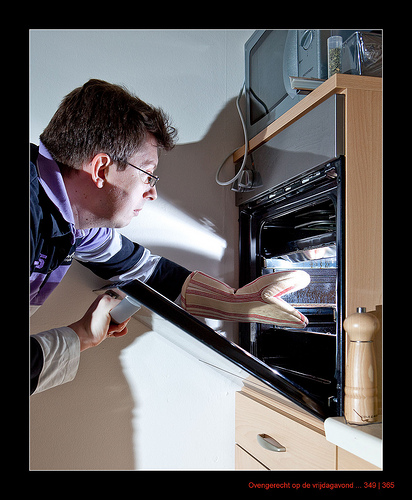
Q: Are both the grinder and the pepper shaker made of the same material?
A: Yes, both the grinder and the pepper shaker are made of wood.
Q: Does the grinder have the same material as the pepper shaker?
A: Yes, both the grinder and the pepper shaker are made of wood.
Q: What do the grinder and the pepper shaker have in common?
A: The material, both the grinder and the pepper shaker are wooden.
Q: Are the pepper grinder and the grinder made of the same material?
A: Yes, both the pepper grinder and the grinder are made of wood.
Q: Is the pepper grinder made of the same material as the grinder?
A: Yes, both the pepper grinder and the grinder are made of wood.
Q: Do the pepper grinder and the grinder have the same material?
A: Yes, both the pepper grinder and the grinder are made of wood.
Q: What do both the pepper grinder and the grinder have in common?
A: The material, both the pepper grinder and the grinder are wooden.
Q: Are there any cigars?
A: No, there are no cigars.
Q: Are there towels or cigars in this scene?
A: No, there are no cigars or towels.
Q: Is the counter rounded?
A: Yes, the counter is rounded.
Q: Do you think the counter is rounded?
A: Yes, the counter is rounded.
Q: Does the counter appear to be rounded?
A: Yes, the counter is rounded.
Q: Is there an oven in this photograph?
A: Yes, there is an oven.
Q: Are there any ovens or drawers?
A: Yes, there is an oven.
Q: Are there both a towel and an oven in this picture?
A: No, there is an oven but no towels.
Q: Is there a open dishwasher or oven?
A: Yes, there is an open oven.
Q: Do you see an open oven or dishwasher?
A: Yes, there is an open oven.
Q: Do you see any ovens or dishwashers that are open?
A: Yes, the oven is open.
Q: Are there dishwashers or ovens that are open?
A: Yes, the oven is open.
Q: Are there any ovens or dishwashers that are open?
A: Yes, the oven is open.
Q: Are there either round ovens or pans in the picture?
A: Yes, there is a round oven.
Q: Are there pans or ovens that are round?
A: Yes, the oven is round.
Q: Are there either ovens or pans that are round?
A: Yes, the oven is round.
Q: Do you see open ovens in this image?
A: Yes, there is an open oven.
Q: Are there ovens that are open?
A: Yes, there is an oven that is open.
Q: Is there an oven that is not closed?
A: Yes, there is a open oven.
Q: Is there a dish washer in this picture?
A: No, there are no dishwashers.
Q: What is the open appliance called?
A: The appliance is an oven.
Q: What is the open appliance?
A: The appliance is an oven.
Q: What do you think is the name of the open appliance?
A: The appliance is an oven.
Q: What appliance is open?
A: The appliance is an oven.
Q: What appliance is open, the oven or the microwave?
A: The oven is open.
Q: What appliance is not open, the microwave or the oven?
A: The microwave is not open.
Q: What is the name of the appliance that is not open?
A: The appliance is a microwave.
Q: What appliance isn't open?
A: The appliance is a microwave.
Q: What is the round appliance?
A: The appliance is an oven.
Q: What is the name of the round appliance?
A: The appliance is an oven.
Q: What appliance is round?
A: The appliance is an oven.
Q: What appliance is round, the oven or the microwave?
A: The oven is round.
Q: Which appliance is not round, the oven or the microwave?
A: The microwave is not round.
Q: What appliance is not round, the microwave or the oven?
A: The microwave is not round.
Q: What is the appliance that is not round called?
A: The appliance is a microwave.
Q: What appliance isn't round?
A: The appliance is a microwave.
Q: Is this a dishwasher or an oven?
A: This is an oven.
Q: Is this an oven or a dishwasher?
A: This is an oven.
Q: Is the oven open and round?
A: Yes, the oven is open and round.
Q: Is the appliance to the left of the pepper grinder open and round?
A: Yes, the oven is open and round.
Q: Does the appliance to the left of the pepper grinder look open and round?
A: Yes, the oven is open and round.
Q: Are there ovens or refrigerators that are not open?
A: No, there is an oven but it is open.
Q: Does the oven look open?
A: Yes, the oven is open.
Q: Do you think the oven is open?
A: Yes, the oven is open.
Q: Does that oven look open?
A: Yes, the oven is open.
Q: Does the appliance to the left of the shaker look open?
A: Yes, the oven is open.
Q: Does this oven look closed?
A: No, the oven is open.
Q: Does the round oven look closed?
A: No, the oven is open.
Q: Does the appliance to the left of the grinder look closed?
A: No, the oven is open.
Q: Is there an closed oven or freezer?
A: No, there is an oven but it is open.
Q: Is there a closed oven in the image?
A: No, there is an oven but it is open.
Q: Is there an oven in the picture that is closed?
A: No, there is an oven but it is open.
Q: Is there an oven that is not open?
A: No, there is an oven but it is open.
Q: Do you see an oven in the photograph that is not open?
A: No, there is an oven but it is open.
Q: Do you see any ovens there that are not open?
A: No, there is an oven but it is open.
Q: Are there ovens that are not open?
A: No, there is an oven but it is open.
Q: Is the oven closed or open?
A: The oven is open.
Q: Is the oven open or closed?
A: The oven is open.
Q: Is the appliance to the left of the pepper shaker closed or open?
A: The oven is open.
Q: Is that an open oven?
A: Yes, that is an open oven.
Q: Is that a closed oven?
A: No, that is an open oven.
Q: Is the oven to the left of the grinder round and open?
A: Yes, the oven is round and open.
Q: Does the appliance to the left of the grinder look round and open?
A: Yes, the oven is round and open.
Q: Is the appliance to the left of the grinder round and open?
A: Yes, the oven is round and open.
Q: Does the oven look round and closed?
A: No, the oven is round but open.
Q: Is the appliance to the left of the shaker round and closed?
A: No, the oven is round but open.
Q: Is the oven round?
A: Yes, the oven is round.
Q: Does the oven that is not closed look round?
A: Yes, the oven is round.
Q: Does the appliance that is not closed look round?
A: Yes, the oven is round.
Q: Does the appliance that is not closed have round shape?
A: Yes, the oven is round.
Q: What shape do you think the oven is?
A: The oven is round.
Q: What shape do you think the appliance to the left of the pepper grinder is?
A: The oven is round.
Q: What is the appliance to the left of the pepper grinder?
A: The appliance is an oven.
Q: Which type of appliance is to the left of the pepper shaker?
A: The appliance is an oven.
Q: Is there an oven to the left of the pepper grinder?
A: Yes, there is an oven to the left of the pepper grinder.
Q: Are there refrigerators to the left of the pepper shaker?
A: No, there is an oven to the left of the pepper shaker.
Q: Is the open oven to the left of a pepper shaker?
A: Yes, the oven is to the left of a pepper shaker.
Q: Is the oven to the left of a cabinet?
A: No, the oven is to the left of a pepper shaker.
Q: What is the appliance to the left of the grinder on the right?
A: The appliance is an oven.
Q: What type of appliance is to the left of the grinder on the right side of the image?
A: The appliance is an oven.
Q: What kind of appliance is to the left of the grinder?
A: The appliance is an oven.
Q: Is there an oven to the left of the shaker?
A: Yes, there is an oven to the left of the shaker.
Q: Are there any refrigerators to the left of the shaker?
A: No, there is an oven to the left of the shaker.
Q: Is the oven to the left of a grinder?
A: Yes, the oven is to the left of a grinder.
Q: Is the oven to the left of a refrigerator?
A: No, the oven is to the left of a grinder.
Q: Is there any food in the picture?
A: No, there is no food.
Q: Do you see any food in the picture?
A: No, there is no food.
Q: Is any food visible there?
A: No, there is no food.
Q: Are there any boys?
A: No, there are no boys.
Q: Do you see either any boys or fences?
A: No, there are no boys or fences.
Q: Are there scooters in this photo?
A: No, there are no scooters.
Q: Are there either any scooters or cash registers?
A: No, there are no scooters or cash registers.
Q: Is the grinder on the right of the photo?
A: Yes, the grinder is on the right of the image.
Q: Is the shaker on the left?
A: No, the shaker is on the right of the image.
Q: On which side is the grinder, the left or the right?
A: The grinder is on the right of the image.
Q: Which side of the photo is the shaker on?
A: The shaker is on the right of the image.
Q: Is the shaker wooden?
A: Yes, the shaker is wooden.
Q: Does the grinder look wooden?
A: Yes, the grinder is wooden.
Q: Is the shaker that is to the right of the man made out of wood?
A: Yes, the grinder is made of wood.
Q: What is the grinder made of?
A: The shaker is made of wood.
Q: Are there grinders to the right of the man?
A: Yes, there is a grinder to the right of the man.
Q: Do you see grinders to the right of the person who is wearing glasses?
A: Yes, there is a grinder to the right of the man.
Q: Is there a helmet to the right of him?
A: No, there is a grinder to the right of the man.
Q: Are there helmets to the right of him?
A: No, there is a grinder to the right of the man.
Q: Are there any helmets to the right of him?
A: No, there is a grinder to the right of the man.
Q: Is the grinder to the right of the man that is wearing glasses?
A: Yes, the grinder is to the right of the man.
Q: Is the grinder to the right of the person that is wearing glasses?
A: Yes, the grinder is to the right of the man.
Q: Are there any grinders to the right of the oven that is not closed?
A: Yes, there is a grinder to the right of the oven.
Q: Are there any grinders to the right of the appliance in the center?
A: Yes, there is a grinder to the right of the oven.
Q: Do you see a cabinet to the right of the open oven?
A: No, there is a grinder to the right of the oven.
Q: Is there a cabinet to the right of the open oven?
A: No, there is a grinder to the right of the oven.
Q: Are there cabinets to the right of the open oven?
A: No, there is a grinder to the right of the oven.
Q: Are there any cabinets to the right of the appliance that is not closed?
A: No, there is a grinder to the right of the oven.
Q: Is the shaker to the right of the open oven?
A: Yes, the shaker is to the right of the oven.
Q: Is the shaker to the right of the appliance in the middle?
A: Yes, the shaker is to the right of the oven.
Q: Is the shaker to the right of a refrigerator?
A: No, the shaker is to the right of the oven.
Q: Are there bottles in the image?
A: No, there are no bottles.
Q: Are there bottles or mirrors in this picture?
A: No, there are no bottles or mirrors.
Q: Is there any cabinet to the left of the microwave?
A: No, there are glasses to the left of the microwave.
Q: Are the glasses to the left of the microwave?
A: Yes, the glasses are to the left of the microwave.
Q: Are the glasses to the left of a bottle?
A: No, the glasses are to the left of the microwave.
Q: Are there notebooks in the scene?
A: No, there are no notebooks.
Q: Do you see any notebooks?
A: No, there are no notebooks.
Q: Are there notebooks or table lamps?
A: No, there are no notebooks or table lamps.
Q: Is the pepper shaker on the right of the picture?
A: Yes, the pepper shaker is on the right of the image.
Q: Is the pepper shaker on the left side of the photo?
A: No, the pepper shaker is on the right of the image.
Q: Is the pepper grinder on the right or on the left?
A: The pepper grinder is on the right of the image.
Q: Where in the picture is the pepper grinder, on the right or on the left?
A: The pepper grinder is on the right of the image.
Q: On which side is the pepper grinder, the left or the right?
A: The pepper grinder is on the right of the image.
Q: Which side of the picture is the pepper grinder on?
A: The pepper grinder is on the right of the image.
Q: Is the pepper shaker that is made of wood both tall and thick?
A: Yes, the pepper grinder is tall and thick.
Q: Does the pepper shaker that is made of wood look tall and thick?
A: Yes, the pepper grinder is tall and thick.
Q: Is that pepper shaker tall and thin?
A: No, the pepper shaker is tall but thick.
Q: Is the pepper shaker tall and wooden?
A: Yes, the pepper shaker is tall and wooden.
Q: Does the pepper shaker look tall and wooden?
A: Yes, the pepper shaker is tall and wooden.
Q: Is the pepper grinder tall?
A: Yes, the pepper grinder is tall.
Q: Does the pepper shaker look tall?
A: Yes, the pepper shaker is tall.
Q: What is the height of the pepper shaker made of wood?
A: The pepper grinder is tall.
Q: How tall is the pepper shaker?
A: The pepper shaker is tall.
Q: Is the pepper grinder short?
A: No, the pepper grinder is tall.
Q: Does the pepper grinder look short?
A: No, the pepper grinder is tall.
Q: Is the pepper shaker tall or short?
A: The pepper shaker is tall.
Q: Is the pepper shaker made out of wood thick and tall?
A: Yes, the pepper grinder is thick and tall.